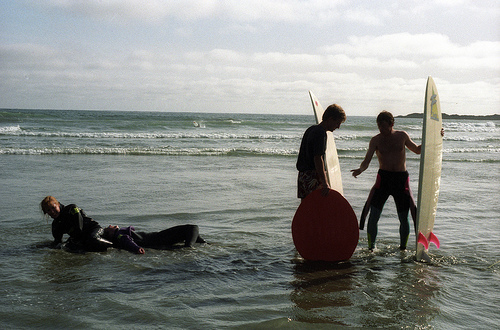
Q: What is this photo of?
A: Men on a beach.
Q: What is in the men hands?
A: Surfboards.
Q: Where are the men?
A: In the water.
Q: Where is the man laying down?
A: Behind the men standing up.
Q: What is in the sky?
A: Clouds.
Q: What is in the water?
A: Waves.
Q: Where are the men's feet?
A: In the water.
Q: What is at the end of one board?
A: Pink flags.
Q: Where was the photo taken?
A: On a beach.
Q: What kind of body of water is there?
A: An ocean.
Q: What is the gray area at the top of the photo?
A: The sky.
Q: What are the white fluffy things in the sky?
A: Clouds.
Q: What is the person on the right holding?
A: A surfboard.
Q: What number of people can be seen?
A: Four.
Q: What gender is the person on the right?
A: Male.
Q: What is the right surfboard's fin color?
A: Pink.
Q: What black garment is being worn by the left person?
A: A wetsuit.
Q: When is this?
A: Daytime.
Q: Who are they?
A: Surfers.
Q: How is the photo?
A: Clear.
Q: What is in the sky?
A: Clouds.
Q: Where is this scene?
A: At the beach.